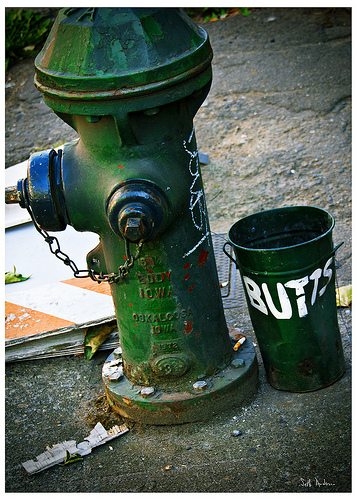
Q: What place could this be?
A: It is a sidewalk.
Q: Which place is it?
A: It is a sidewalk.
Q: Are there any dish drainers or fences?
A: No, there are no fences or dish drainers.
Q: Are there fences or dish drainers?
A: No, there are no fences or dish drainers.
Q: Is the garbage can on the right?
A: Yes, the garbage can is on the right of the image.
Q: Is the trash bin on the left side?
A: No, the trash bin is on the right of the image.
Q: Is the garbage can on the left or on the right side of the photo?
A: The garbage can is on the right of the image.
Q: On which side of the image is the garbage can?
A: The garbage can is on the right of the image.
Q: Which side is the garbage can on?
A: The garbage can is on the right of the image.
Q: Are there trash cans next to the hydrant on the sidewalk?
A: Yes, there is a trash can next to the hydrant.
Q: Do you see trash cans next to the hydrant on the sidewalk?
A: Yes, there is a trash can next to the hydrant.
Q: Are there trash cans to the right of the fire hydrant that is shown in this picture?
A: Yes, there is a trash can to the right of the fire hydrant.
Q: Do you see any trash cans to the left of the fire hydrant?
A: No, the trash can is to the right of the fire hydrant.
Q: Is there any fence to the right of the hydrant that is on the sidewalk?
A: No, there is a trash can to the right of the hydrant.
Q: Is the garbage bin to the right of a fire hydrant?
A: Yes, the garbage bin is to the right of a fire hydrant.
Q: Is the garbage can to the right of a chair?
A: No, the garbage can is to the right of a fire hydrant.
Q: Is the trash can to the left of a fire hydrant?
A: No, the trash can is to the right of a fire hydrant.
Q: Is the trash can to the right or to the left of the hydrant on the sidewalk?
A: The trash can is to the right of the fire hydrant.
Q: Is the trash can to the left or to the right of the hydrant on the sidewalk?
A: The trash can is to the right of the fire hydrant.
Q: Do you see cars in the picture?
A: No, there are no cars.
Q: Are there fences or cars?
A: No, there are no cars or fences.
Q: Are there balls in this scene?
A: No, there are no balls.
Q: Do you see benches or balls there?
A: No, there are no balls or benches.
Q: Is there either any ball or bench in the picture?
A: No, there are no balls or benches.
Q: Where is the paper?
A: The paper is on the sidewalk.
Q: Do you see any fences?
A: No, there are no fences.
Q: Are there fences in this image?
A: No, there are no fences.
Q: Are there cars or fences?
A: No, there are no fences or cars.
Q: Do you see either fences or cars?
A: No, there are no fences or cars.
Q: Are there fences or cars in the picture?
A: No, there are no fences or cars.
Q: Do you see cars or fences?
A: No, there are no fences or cars.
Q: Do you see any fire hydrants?
A: Yes, there is a fire hydrant.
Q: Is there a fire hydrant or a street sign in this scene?
A: Yes, there is a fire hydrant.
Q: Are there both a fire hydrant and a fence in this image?
A: No, there is a fire hydrant but no fences.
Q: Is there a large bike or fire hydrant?
A: Yes, there is a large fire hydrant.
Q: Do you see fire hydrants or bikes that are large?
A: Yes, the fire hydrant is large.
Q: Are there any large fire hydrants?
A: Yes, there is a large fire hydrant.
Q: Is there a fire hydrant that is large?
A: Yes, there is a fire hydrant that is large.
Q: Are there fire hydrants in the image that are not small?
A: Yes, there is a large fire hydrant.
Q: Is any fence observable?
A: No, there are no fences.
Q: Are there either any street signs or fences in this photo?
A: No, there are no fences or street signs.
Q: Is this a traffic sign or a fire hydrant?
A: This is a fire hydrant.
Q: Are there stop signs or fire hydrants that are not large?
A: No, there is a fire hydrant but it is large.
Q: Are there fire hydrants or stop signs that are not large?
A: No, there is a fire hydrant but it is large.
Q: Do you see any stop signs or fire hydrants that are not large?
A: No, there is a fire hydrant but it is large.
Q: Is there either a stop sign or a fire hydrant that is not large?
A: No, there is a fire hydrant but it is large.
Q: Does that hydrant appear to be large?
A: Yes, the hydrant is large.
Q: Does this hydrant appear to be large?
A: Yes, the hydrant is large.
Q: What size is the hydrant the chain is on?
A: The fire hydrant is large.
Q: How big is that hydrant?
A: The hydrant is large.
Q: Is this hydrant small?
A: No, the hydrant is large.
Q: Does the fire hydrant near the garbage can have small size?
A: No, the fire hydrant is large.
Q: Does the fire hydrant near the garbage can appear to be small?
A: No, the fire hydrant is large.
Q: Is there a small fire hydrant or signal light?
A: No, there is a fire hydrant but it is large.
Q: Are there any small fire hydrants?
A: No, there is a fire hydrant but it is large.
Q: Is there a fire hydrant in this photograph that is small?
A: No, there is a fire hydrant but it is large.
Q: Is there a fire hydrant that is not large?
A: No, there is a fire hydrant but it is large.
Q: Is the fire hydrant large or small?
A: The fire hydrant is large.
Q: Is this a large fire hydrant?
A: Yes, this is a large fire hydrant.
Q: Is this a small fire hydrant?
A: No, this is a large fire hydrant.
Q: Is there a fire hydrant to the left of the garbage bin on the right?
A: Yes, there is a fire hydrant to the left of the trash bin.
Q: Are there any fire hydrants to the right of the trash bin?
A: No, the fire hydrant is to the left of the trash bin.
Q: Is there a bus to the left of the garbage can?
A: No, there is a fire hydrant to the left of the garbage can.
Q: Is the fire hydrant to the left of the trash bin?
A: Yes, the fire hydrant is to the left of the trash bin.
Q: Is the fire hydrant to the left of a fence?
A: No, the fire hydrant is to the left of the trash bin.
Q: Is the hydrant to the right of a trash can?
A: No, the hydrant is to the left of a trash can.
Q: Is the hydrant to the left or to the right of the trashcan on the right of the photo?
A: The hydrant is to the left of the trashcan.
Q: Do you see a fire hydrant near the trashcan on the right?
A: Yes, there is a fire hydrant near the garbage bin.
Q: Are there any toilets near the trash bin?
A: No, there is a fire hydrant near the trash bin.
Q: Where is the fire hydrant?
A: The fire hydrant is on the sidewalk.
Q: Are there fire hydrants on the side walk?
A: Yes, there is a fire hydrant on the side walk.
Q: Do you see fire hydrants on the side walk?
A: Yes, there is a fire hydrant on the side walk.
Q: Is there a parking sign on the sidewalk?
A: No, there is a fire hydrant on the sidewalk.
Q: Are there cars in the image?
A: No, there are no cars.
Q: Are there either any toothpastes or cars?
A: No, there are no cars or toothpastes.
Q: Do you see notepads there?
A: No, there are no notepads.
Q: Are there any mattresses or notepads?
A: No, there are no notepads or mattresses.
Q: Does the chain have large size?
A: Yes, the chain is large.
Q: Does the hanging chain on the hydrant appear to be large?
A: Yes, the chain is large.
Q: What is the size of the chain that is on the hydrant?
A: The chain is large.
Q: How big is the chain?
A: The chain is large.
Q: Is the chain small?
A: No, the chain is large.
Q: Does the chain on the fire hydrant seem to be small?
A: No, the chain is large.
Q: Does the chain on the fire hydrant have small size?
A: No, the chain is large.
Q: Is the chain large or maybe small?
A: The chain is large.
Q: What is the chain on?
A: The chain is on the hydrant.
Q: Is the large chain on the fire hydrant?
A: Yes, the chain is on the fire hydrant.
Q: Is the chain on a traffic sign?
A: No, the chain is on the fire hydrant.